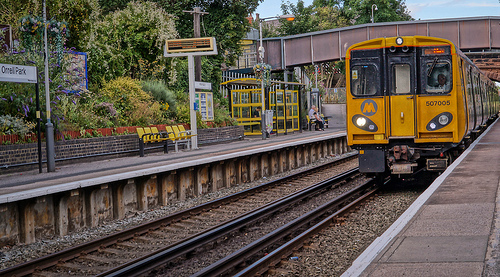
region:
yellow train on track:
[339, 35, 498, 174]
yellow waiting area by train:
[213, 73, 310, 137]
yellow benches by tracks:
[130, 124, 192, 146]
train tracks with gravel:
[23, 183, 406, 273]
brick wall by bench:
[1, 127, 246, 182]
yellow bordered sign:
[164, 34, 214, 55]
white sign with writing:
[1, 63, 41, 84]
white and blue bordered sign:
[55, 51, 90, 94]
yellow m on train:
[358, 100, 382, 115]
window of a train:
[350, 53, 385, 105]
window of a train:
[388, 57, 426, 97]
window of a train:
[420, 60, 453, 93]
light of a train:
[420, 113, 462, 130]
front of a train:
[357, 139, 471, 186]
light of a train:
[392, 25, 406, 45]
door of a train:
[372, 37, 422, 164]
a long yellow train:
[325, 22, 497, 187]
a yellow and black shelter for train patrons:
[215, 61, 311, 142]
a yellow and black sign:
[153, 32, 242, 77]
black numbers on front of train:
[424, 96, 452, 116]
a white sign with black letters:
[3, 60, 43, 88]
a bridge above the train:
[284, 14, 496, 66]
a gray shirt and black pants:
[302, 97, 341, 157]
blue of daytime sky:
[251, 1, 497, 26]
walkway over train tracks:
[278, 16, 499, 144]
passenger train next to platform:
[350, 34, 495, 166]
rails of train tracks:
[24, 173, 376, 275]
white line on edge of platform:
[348, 122, 498, 274]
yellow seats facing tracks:
[134, 123, 191, 155]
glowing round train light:
[352, 113, 367, 128]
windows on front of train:
[353, 44, 453, 97]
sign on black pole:
[2, 63, 42, 173]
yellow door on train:
[385, 48, 417, 136]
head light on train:
[353, 114, 376, 136]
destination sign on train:
[423, 46, 448, 58]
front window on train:
[352, 62, 379, 98]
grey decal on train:
[358, 99, 377, 119]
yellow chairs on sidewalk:
[136, 126, 167, 153]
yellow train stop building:
[221, 76, 301, 138]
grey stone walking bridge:
[261, 13, 498, 71]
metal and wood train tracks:
[1, 154, 376, 271]